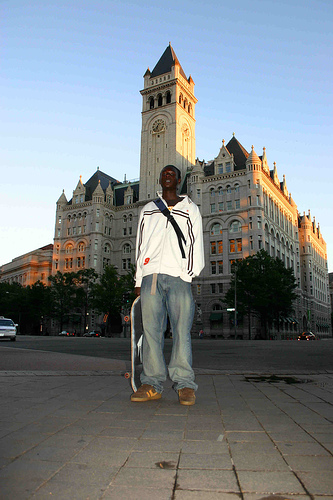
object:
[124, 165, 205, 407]
man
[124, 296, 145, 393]
skateboard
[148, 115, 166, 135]
clock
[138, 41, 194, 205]
tower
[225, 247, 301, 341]
tree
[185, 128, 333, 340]
building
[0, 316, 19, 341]
car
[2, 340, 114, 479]
street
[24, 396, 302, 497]
sidewalk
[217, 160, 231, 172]
window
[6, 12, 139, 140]
sky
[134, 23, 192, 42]
distance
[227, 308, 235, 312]
sign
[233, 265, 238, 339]
pole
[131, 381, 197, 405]
brown sneakers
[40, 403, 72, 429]
part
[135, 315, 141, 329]
part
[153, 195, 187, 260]
strap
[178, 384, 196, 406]
shoe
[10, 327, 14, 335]
part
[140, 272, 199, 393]
jeans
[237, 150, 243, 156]
part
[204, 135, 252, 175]
roof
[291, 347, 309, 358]
part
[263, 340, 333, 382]
roadway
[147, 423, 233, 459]
bricks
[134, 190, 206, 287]
white jacket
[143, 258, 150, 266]
number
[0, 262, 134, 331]
trees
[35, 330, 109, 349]
sidewalk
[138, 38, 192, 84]
spire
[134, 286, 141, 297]
hand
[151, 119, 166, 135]
face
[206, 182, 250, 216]
windows